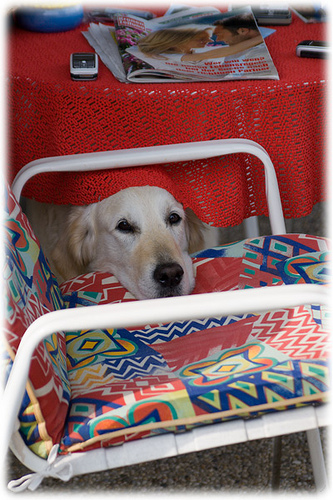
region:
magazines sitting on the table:
[88, 18, 274, 85]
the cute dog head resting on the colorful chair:
[62, 187, 209, 302]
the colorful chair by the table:
[4, 183, 316, 451]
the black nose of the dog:
[153, 259, 182, 287]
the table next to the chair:
[13, 12, 326, 217]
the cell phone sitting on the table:
[69, 52, 98, 79]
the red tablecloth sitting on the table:
[10, 36, 329, 222]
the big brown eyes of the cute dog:
[115, 211, 183, 235]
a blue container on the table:
[17, 6, 85, 32]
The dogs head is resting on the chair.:
[49, 175, 235, 292]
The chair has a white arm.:
[17, 136, 272, 179]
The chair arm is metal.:
[18, 140, 272, 173]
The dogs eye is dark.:
[158, 205, 185, 229]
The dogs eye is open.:
[158, 207, 183, 226]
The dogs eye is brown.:
[161, 205, 184, 231]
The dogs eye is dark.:
[105, 213, 142, 238]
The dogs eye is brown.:
[109, 214, 142, 238]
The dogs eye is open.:
[111, 211, 138, 237]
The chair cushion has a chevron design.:
[265, 311, 330, 355]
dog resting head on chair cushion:
[19, 189, 228, 309]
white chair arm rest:
[14, 272, 324, 499]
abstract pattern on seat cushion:
[57, 267, 325, 424]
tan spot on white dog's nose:
[130, 224, 183, 269]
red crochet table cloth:
[8, 28, 320, 240]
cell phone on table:
[56, 46, 105, 84]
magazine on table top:
[107, 9, 280, 89]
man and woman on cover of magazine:
[138, 4, 257, 53]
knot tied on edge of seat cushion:
[3, 443, 84, 492]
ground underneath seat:
[79, 433, 316, 499]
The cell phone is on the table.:
[56, 45, 103, 87]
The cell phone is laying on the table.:
[293, 33, 327, 62]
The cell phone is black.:
[62, 44, 100, 83]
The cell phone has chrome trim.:
[64, 40, 102, 85]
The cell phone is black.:
[290, 35, 325, 61]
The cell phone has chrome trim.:
[295, 37, 327, 57]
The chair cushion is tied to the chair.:
[7, 425, 107, 488]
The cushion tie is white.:
[13, 432, 95, 499]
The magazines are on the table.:
[100, 12, 284, 90]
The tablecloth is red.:
[32, 82, 297, 143]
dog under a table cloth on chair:
[30, 181, 234, 311]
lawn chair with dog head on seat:
[16, 138, 331, 495]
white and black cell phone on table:
[67, 45, 110, 85]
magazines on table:
[93, 2, 291, 105]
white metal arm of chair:
[22, 128, 257, 190]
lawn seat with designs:
[60, 269, 325, 417]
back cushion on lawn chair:
[0, 150, 70, 434]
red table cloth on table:
[261, 95, 316, 148]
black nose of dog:
[151, 251, 187, 289]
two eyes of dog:
[103, 203, 190, 245]